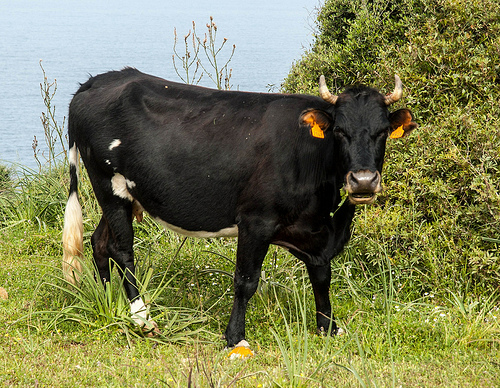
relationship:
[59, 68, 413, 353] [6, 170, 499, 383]
bull in grass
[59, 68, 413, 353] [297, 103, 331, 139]
bull has ear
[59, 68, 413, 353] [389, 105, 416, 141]
bull has ear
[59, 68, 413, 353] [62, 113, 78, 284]
bull has tail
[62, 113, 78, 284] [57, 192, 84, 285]
tail has hair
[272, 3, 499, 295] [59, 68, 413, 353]
tree behind bull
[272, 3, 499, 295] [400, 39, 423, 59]
tree has wild flower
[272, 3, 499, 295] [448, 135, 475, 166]
tree has wild flower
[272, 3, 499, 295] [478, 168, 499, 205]
tree has wild flower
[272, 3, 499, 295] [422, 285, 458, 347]
tree has wild flower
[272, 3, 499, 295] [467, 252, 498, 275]
tree has wild flower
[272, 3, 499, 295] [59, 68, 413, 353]
tree next to bull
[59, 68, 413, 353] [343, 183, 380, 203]
bull has mouth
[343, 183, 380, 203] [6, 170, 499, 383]
mouth full of grass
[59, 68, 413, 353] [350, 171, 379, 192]
bull has nose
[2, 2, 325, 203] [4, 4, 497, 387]
stream next to field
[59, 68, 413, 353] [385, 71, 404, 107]
bull has horn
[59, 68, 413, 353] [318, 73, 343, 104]
bull has horn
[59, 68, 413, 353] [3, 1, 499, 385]
bull in photo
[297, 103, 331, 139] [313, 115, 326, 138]
ear has id tag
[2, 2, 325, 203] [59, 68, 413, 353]
stream behind bull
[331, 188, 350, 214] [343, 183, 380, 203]
grass hanging from mouth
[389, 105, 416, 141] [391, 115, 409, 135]
ear has id tag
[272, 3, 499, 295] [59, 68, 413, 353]
tree right of bull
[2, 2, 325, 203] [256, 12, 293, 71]
stream has a part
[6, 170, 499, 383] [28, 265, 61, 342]
grass has a part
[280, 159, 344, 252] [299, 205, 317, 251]
chest has a part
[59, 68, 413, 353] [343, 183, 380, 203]
bull has a mouth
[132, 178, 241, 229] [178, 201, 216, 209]
stomach has a part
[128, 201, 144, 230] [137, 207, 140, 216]
udder has a part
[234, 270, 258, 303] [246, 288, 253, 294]
knee has a part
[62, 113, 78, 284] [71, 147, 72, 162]
tail has a part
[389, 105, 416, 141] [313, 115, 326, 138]
ear has id tag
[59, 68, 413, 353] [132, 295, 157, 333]
bull has foot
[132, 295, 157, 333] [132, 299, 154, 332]
foot has spot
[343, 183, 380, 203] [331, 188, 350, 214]
mouth chewing grass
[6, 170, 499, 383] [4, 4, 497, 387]
grass in field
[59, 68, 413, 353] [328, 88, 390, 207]
bull has head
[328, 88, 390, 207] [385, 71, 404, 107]
head has horn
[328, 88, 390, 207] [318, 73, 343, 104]
head has horn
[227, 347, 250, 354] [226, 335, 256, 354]
id tag on hoof